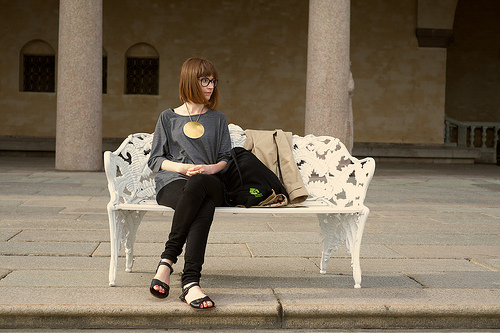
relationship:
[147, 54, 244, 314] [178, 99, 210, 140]
woman wearing necklace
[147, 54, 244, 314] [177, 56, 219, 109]
woman has hair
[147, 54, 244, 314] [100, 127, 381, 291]
woman sitting on bench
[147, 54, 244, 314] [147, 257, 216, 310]
woman wearing shoes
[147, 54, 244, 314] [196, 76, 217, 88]
woman wearing glasses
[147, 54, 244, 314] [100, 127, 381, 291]
woman with bench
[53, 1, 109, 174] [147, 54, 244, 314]
column behind woman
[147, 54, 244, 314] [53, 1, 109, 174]
woman in front of column